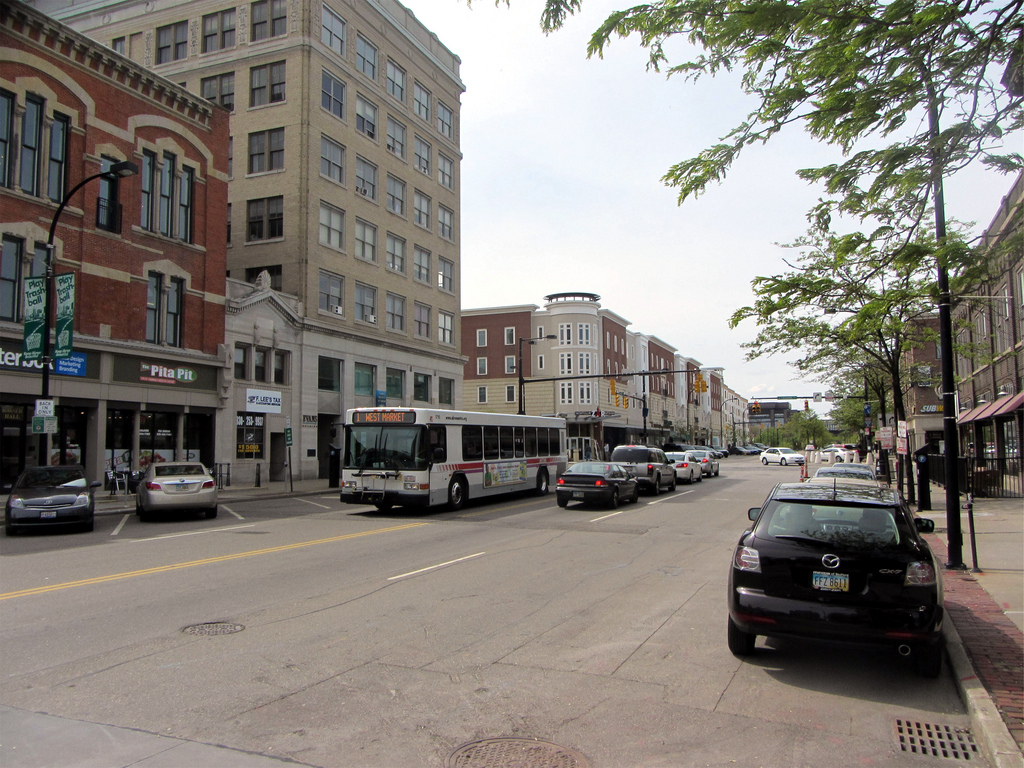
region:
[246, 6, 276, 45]
a window on a building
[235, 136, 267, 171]
a window on a building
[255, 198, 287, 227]
a window on a building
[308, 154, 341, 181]
a window on a building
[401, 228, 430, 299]
a window on a building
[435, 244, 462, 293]
a window on a building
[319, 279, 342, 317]
a window on a building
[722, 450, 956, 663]
car on a street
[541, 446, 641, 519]
car on the street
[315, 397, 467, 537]
bus on a street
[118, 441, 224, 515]
car parked on a street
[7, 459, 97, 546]
car parked in a street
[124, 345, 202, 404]
sign on a building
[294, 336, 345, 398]
window on a building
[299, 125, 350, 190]
window on a building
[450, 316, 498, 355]
window on a building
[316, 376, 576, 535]
a white and red bus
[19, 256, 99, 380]
two green and white banners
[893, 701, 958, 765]
a sewer grate in the road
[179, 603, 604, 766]
two man hole covers in the road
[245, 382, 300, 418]
a white and black sign on the building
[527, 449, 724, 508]
four cars stopped at the light.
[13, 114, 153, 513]
a black pole with a street light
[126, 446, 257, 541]
a silver parked car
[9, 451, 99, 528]
a dark gray parked car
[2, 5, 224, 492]
a three story building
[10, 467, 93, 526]
the car is parked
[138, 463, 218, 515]
a car is parked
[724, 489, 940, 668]
the car is black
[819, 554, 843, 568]
logo on the car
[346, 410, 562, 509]
bus on the road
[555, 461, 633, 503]
a car is stopping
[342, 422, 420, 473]
windshield of the bus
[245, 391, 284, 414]
sign on the building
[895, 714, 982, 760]
sewer vent on road